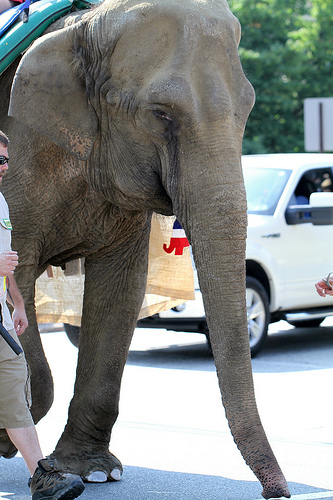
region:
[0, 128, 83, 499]
a man walking beside an elephant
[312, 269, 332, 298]
part of a human hand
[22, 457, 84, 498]
a black and brown iking boot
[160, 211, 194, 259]
part of the Republican GOP party elephant logo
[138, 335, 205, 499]
a section a gray asphalt street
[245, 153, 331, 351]
part of the front of a white vehicle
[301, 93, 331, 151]
the back of a street sign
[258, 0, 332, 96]
green leaves on trees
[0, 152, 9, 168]
dark tinted sunglasses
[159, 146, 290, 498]
the trunk of an elephant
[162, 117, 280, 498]
elephant trunk hanging down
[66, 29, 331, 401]
elephant crossing the street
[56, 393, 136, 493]
elephant foot and nails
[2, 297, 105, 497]
person walking by elephant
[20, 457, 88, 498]
black and brown shoe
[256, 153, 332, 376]
white vehicle on road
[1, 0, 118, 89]
turquoise mat on elephant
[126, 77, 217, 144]
elephant eye is open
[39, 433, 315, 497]
shadow of elephant on street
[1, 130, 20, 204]
guy wearing dark sunglasses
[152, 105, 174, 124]
an elephant eye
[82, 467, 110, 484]
a white elephant toenail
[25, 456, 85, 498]
a brown and black shoe on a man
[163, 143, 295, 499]
a long elephant trunk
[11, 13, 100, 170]
an elephant ear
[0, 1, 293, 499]
an elephant crossing a road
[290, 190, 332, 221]
a grey sideview mirror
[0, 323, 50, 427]
brown shorts on a man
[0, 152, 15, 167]
sunglasses on a man's face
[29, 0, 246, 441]
this is an elephant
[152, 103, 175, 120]
the eye is open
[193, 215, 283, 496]
this is the trunk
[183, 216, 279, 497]
the trunk is long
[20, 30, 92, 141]
the ear is short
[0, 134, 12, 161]
this is a man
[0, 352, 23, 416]
he is wearing shorts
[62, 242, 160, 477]
this is a leg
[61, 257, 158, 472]
the leg is big in size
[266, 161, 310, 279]
this is a truck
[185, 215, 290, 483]
hanging trunk of elephant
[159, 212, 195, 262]
red, white and blue emblem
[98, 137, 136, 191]
wrinkled skin on elephant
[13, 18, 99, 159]
ear on elephant head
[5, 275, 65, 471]
walking man in shorts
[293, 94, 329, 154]
back of sign on post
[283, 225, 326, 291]
door of white vehicle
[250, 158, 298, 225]
glare on vehicle windshield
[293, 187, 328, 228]
sideview mirror on vehicle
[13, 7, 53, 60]
green cushion on elephant